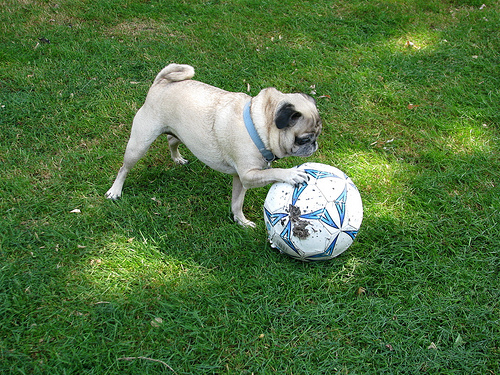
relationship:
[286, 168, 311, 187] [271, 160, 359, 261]
foot on ball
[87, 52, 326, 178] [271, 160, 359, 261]
dog playing with ball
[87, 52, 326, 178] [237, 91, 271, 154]
dog has collar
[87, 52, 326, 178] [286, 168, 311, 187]
dog has foot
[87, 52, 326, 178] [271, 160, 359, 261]
dog touches ball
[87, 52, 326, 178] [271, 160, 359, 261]
dog ear ball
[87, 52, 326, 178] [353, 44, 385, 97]
dog of grass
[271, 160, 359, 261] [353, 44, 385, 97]
ball of grass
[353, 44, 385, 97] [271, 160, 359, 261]
grass ear ball